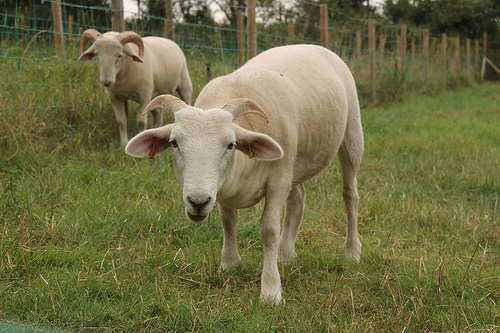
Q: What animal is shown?
A: Sheep.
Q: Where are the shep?
A: In the field.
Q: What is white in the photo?
A: Sheep.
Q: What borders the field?
A: Fence.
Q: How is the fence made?
A: Of wood.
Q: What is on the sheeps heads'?
A: Horns.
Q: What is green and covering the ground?
A: Grass.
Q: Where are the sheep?
A: Behind the fence.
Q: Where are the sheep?
A: Behind the fence.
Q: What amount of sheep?
A: Two.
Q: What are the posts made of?
A: Wooden.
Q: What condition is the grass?
A: Lush.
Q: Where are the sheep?
A: Pasture.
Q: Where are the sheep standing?
A: Grass.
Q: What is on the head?
A: Horns.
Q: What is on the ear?
A: Tag.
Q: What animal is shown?
A: A goat.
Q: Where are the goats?
A: In a field.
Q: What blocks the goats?
A: A fence.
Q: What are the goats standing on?
A: Grass.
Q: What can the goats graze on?
A: The grass.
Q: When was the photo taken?
A: During the day time.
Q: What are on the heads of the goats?
A: Horns.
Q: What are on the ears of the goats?
A: Tags.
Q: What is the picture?
A: Goats.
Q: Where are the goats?
A: Field.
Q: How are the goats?
A: Standing.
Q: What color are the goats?
A: White.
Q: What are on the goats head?
A: Horns.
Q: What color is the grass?
A: Green.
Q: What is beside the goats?
A: Fence.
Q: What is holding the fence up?
A: Fence post.